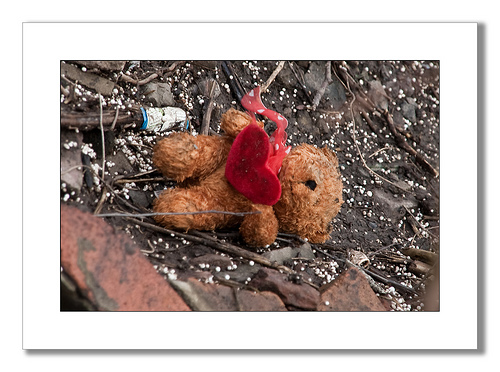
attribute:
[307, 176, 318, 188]
nose — button, black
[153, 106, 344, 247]
bear — stuffed, toy, teddy, lying, little, old, holding, laying, brown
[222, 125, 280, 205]
heart — dirty, red, large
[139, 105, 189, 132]
can — empty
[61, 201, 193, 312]
brick — red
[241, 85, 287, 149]
ribbon — red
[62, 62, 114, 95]
wood — laying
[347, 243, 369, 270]
trash — blue, assorted, more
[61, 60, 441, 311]
ground — rocky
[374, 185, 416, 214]
rock — brown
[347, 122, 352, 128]
pieces — white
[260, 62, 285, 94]
branches — dead